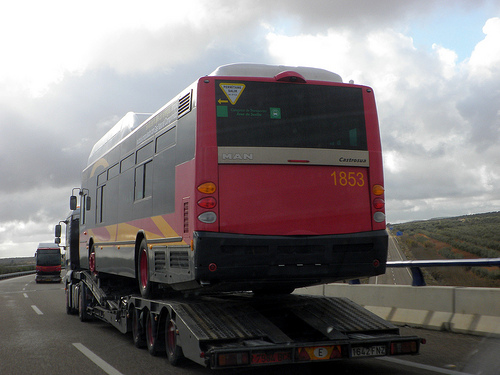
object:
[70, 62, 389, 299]
bus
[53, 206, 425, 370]
truck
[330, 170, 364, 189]
number 1853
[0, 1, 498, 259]
sky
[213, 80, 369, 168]
window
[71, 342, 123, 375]
lines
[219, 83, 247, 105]
sign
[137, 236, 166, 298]
tire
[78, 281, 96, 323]
wheels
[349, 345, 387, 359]
license plate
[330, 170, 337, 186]
numbers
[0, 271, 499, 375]
highway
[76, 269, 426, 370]
flat bed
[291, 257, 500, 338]
gaurdrail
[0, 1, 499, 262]
clouds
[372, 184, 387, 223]
break lights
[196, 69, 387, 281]
back of bus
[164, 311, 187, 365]
tires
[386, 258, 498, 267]
rail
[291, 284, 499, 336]
concrete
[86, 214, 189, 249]
strip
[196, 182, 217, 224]
tail light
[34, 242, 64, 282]
truck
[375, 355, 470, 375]
line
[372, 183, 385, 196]
yellow light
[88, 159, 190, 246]
design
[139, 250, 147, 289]
red rim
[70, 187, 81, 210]
side mirror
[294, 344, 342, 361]
yellow license plate